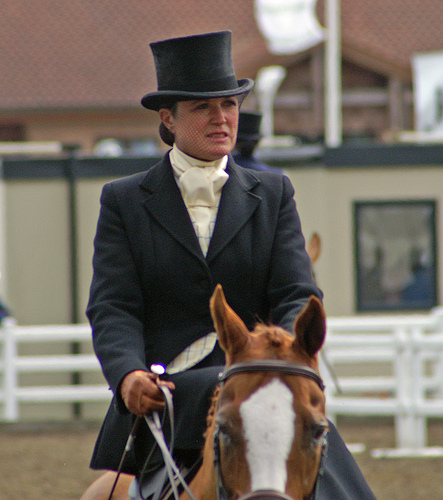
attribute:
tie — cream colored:
[166, 142, 234, 248]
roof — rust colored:
[5, 0, 442, 110]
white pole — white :
[328, 7, 347, 157]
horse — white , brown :
[181, 285, 357, 496]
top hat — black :
[127, 26, 257, 110]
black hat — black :
[138, 27, 258, 108]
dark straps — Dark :
[210, 357, 330, 497]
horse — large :
[176, 273, 345, 496]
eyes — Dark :
[217, 405, 340, 446]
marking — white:
[239, 374, 300, 496]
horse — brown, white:
[80, 282, 328, 497]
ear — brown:
[291, 287, 327, 353]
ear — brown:
[208, 282, 252, 360]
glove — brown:
[121, 367, 176, 419]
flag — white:
[252, 0, 336, 58]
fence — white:
[0, 302, 443, 461]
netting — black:
[155, 99, 240, 164]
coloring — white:
[233, 371, 299, 496]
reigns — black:
[137, 380, 197, 496]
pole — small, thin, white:
[320, 0, 344, 149]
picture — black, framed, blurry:
[346, 198, 428, 312]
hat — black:
[135, 25, 256, 110]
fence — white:
[1, 310, 425, 457]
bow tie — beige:
[167, 142, 234, 212]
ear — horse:
[204, 281, 245, 350]